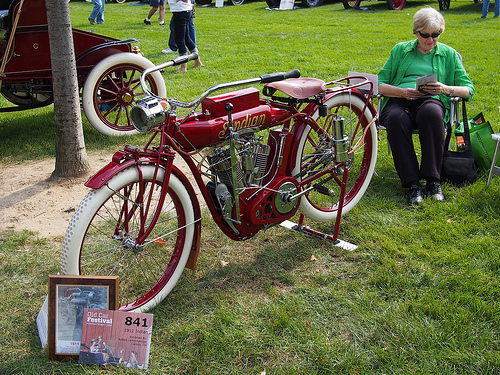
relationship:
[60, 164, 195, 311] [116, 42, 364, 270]
tire of bicycle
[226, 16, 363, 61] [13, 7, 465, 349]
grass on field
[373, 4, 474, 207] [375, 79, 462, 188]
lady sitting in a chair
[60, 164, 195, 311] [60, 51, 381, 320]
tire of bike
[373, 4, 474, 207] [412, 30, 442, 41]
lady wears sunglasses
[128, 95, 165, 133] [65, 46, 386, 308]
headlight on bicycle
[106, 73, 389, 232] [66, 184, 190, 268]
bike has tire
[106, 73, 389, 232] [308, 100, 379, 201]
bike has tire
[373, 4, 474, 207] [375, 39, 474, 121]
lady wearing shirt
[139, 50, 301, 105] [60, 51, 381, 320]
handle bars is on bike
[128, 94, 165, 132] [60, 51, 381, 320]
headlight of bike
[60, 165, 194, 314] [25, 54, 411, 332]
tire on bike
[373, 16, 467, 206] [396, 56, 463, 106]
lady wearing tshirt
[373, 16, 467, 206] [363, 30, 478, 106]
lady wearing shirt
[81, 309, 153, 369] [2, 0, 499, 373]
book on grass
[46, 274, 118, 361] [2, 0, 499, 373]
frame on grass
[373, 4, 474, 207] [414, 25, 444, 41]
lady wearing sunglasses